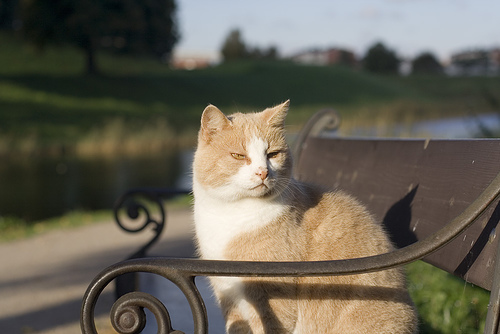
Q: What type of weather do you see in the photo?
A: It is clear.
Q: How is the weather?
A: It is clear.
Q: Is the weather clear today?
A: Yes, it is clear.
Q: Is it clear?
A: Yes, it is clear.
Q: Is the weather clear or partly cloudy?
A: It is clear.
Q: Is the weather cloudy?
A: No, it is clear.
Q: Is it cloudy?
A: No, it is clear.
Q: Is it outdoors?
A: Yes, it is outdoors.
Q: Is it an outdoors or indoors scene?
A: It is outdoors.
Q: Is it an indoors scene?
A: No, it is outdoors.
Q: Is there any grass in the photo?
A: Yes, there is grass.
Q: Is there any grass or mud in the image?
A: Yes, there is grass.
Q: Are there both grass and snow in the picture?
A: No, there is grass but no snow.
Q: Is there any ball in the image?
A: No, there are no balls.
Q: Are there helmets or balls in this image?
A: No, there are no balls or helmets.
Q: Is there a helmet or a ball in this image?
A: No, there are no balls or helmets.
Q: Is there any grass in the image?
A: Yes, there is grass.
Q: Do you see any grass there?
A: Yes, there is grass.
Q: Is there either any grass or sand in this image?
A: Yes, there is grass.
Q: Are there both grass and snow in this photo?
A: No, there is grass but no snow.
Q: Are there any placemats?
A: No, there are no placemats.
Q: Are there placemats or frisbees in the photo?
A: No, there are no placemats or frisbees.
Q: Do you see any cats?
A: Yes, there is a cat.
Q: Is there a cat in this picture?
A: Yes, there is a cat.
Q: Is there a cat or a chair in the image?
A: Yes, there is a cat.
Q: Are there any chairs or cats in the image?
A: Yes, there is a cat.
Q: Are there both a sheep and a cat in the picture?
A: No, there is a cat but no sheep.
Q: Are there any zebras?
A: No, there are no zebras.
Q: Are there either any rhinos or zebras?
A: No, there are no zebras or rhinos.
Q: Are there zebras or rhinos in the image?
A: No, there are no zebras or rhinos.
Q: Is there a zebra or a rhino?
A: No, there are no zebras or rhinos.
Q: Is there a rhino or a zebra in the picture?
A: No, there are no zebras or rhinos.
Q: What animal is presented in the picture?
A: The animal is a cat.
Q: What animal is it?
A: The animal is a cat.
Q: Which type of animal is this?
A: This is a cat.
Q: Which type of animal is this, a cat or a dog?
A: This is a cat.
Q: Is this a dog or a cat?
A: This is a cat.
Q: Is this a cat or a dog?
A: This is a cat.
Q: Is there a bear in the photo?
A: No, there are no bears.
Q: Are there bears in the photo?
A: No, there are no bears.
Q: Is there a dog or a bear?
A: No, there are no bears or dogs.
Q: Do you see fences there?
A: No, there are no fences.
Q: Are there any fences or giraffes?
A: No, there are no fences or giraffes.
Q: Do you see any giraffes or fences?
A: No, there are no fences or giraffes.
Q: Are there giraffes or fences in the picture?
A: No, there are no fences or giraffes.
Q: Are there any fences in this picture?
A: No, there are no fences.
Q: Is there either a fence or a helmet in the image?
A: No, there are no fences or helmets.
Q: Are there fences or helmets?
A: No, there are no fences or helmets.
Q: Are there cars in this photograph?
A: No, there are no cars.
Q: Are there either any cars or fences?
A: No, there are no cars or fences.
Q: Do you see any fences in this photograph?
A: No, there are no fences.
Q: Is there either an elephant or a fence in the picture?
A: No, there are no fences or elephants.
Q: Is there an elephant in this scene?
A: No, there are no elephants.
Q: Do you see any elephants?
A: No, there are no elephants.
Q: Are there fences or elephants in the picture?
A: No, there are no elephants or fences.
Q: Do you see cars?
A: No, there are no cars.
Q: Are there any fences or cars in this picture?
A: No, there are no cars or fences.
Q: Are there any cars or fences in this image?
A: No, there are no cars or fences.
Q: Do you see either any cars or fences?
A: No, there are no cars or fences.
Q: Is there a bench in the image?
A: Yes, there is a bench.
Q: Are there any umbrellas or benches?
A: Yes, there is a bench.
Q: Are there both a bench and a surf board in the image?
A: No, there is a bench but no surfboards.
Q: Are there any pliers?
A: No, there are no pliers.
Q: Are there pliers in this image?
A: No, there are no pliers.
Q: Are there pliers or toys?
A: No, there are no pliers or toys.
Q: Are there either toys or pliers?
A: No, there are no pliers or toys.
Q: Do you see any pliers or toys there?
A: No, there are no pliers or toys.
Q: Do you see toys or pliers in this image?
A: No, there are no pliers or toys.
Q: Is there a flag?
A: No, there are no flags.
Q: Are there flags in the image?
A: No, there are no flags.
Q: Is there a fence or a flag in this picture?
A: No, there are no flags or fences.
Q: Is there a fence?
A: No, there are no fences.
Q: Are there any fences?
A: No, there are no fences.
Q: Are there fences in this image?
A: No, there are no fences.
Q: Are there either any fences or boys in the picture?
A: No, there are no fences or boys.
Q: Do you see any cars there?
A: No, there are no cars.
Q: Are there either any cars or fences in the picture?
A: No, there are no cars or fences.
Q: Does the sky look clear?
A: Yes, the sky is clear.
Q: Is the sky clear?
A: Yes, the sky is clear.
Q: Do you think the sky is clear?
A: Yes, the sky is clear.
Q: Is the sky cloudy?
A: No, the sky is clear.